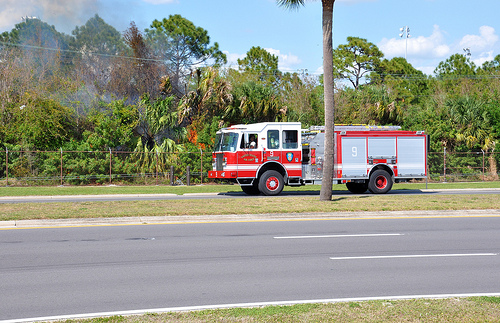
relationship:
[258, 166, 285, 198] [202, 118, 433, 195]
front wheel of truck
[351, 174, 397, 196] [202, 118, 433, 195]
rear wheels of truck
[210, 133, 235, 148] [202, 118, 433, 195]
windshield of truck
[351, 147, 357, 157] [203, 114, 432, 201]
9 on truck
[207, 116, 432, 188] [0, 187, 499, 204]
fire engine on road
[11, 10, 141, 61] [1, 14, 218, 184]
smoke in field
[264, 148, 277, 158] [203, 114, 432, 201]
9 on truck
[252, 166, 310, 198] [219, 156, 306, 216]
rims on tires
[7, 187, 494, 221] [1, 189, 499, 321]
grass dividing street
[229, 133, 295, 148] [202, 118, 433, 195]
firemen carrying truck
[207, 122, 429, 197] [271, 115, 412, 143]
fire engine carrying ladders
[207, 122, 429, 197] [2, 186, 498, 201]
fire engine on sidewalk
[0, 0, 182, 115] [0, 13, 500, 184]
smoke in woods